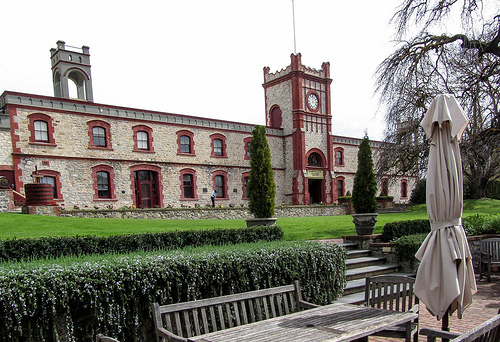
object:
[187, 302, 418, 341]
table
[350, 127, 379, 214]
evergreen tree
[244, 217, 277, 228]
planter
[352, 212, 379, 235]
planter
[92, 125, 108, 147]
window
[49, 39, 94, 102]
pillar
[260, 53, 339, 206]
tower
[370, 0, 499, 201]
tree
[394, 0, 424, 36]
branch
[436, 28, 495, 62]
branch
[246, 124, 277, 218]
bush.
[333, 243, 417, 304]
stairs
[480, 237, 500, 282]
bench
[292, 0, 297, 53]
pole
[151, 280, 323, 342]
bench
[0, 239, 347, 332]
flower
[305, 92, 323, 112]
clock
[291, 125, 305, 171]
red moldings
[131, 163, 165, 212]
window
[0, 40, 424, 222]
building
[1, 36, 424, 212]
estate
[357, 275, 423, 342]
chair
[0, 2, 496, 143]
sky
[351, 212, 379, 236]
vase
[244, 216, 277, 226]
vase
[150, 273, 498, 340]
sitting area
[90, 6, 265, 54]
clouds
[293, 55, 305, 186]
trim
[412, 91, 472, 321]
umbrella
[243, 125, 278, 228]
pots